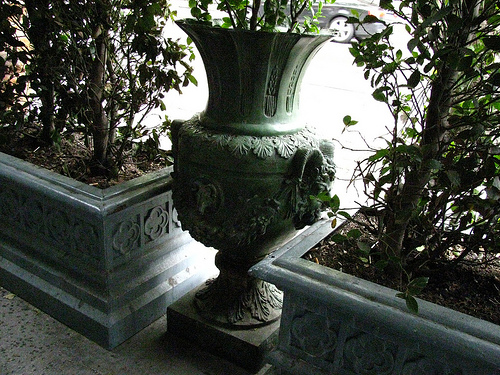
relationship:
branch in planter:
[0, 0, 205, 167] [2, 134, 205, 354]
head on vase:
[189, 178, 218, 216] [171, 14, 340, 331]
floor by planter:
[1, 286, 275, 374] [2, 134, 205, 354]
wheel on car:
[327, 16, 356, 45] [239, 0, 395, 43]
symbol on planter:
[110, 218, 141, 256] [2, 134, 205, 354]